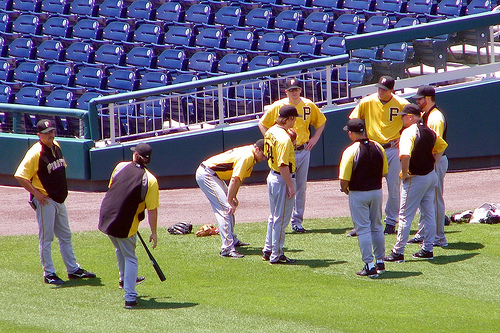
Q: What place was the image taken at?
A: It was taken at the field.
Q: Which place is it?
A: It is a field.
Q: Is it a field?
A: Yes, it is a field.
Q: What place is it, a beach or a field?
A: It is a field.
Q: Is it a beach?
A: No, it is a field.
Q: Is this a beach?
A: No, it is a field.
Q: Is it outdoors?
A: Yes, it is outdoors.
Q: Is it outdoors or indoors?
A: It is outdoors.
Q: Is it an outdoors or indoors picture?
A: It is outdoors.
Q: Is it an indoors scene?
A: No, it is outdoors.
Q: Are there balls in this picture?
A: No, there are no balls.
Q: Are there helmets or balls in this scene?
A: No, there are no balls or helmets.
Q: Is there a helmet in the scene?
A: No, there are no helmets.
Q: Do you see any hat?
A: Yes, there is a hat.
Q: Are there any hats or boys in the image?
A: Yes, there is a hat.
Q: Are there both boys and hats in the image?
A: No, there is a hat but no boys.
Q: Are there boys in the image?
A: No, there are no boys.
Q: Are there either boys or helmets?
A: No, there are no boys or helmets.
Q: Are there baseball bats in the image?
A: Yes, there is a baseball bat.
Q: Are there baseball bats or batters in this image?
A: Yes, there is a baseball bat.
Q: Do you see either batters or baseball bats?
A: Yes, there is a baseball bat.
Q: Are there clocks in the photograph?
A: No, there are no clocks.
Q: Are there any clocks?
A: No, there are no clocks.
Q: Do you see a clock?
A: No, there are no clocks.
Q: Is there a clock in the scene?
A: No, there are no clocks.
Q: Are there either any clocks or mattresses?
A: No, there are no clocks or mattresses.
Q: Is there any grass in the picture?
A: Yes, there is grass.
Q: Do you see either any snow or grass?
A: Yes, there is grass.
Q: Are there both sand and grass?
A: No, there is grass but no sand.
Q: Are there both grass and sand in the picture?
A: No, there is grass but no sand.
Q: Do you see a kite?
A: No, there are no kites.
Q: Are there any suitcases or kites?
A: No, there are no kites or suitcases.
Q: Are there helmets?
A: No, there are no helmets.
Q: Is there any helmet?
A: No, there are no helmets.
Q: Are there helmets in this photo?
A: No, there are no helmets.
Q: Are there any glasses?
A: No, there are no glasses.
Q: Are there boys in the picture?
A: No, there are no boys.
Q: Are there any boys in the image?
A: No, there are no boys.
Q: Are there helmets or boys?
A: No, there are no boys or helmets.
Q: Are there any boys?
A: No, there are no boys.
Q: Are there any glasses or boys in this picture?
A: No, there are no boys or glasses.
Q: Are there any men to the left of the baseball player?
A: Yes, there are men to the left of the player.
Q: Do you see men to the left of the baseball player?
A: Yes, there are men to the left of the player.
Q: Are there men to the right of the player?
A: No, the men are to the left of the player.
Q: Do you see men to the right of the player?
A: No, the men are to the left of the player.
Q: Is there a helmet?
A: No, there are no helmets.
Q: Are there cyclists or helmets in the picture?
A: No, there are no helmets or cyclists.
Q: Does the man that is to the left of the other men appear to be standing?
A: Yes, the man is standing.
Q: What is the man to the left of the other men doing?
A: The man is standing.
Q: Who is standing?
A: The man is standing.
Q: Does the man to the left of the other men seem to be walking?
A: No, the man is standing.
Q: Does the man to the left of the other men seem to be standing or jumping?
A: The man is standing.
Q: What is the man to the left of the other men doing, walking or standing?
A: The man is standing.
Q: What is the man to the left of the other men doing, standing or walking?
A: The man is standing.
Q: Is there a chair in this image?
A: Yes, there is a chair.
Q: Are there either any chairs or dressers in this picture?
A: Yes, there is a chair.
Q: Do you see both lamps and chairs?
A: No, there is a chair but no lamps.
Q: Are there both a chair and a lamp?
A: No, there is a chair but no lamps.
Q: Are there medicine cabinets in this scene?
A: No, there are no medicine cabinets.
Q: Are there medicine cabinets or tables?
A: No, there are no medicine cabinets or tables.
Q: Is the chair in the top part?
A: Yes, the chair is in the top of the image.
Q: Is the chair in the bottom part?
A: No, the chair is in the top of the image.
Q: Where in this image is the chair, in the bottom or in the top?
A: The chair is in the top of the image.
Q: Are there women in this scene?
A: No, there are no women.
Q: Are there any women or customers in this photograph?
A: No, there are no women or customers.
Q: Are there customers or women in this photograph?
A: No, there are no women or customers.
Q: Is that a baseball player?
A: Yes, that is a baseball player.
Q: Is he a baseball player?
A: Yes, that is a baseball player.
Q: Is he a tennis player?
A: No, that is a baseball player.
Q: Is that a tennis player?
A: No, that is a baseball player.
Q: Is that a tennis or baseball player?
A: That is a baseball player.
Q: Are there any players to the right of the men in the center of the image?
A: Yes, there is a player to the right of the men.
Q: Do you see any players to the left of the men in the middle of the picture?
A: No, the player is to the right of the men.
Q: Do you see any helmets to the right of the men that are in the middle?
A: No, there is a player to the right of the men.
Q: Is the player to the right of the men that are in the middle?
A: Yes, the player is to the right of the men.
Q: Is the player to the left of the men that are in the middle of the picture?
A: No, the player is to the right of the men.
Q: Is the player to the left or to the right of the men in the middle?
A: The player is to the right of the men.